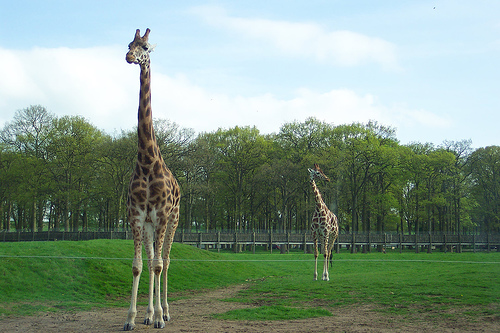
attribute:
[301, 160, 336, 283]
giraffe — very attractive , one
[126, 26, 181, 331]
giraffe — very attractive , one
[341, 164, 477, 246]
trees — green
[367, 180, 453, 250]
set — nice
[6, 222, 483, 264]
fence — wooden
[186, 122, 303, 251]
trees — tall, leafy, green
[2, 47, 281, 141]
clouds — white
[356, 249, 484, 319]
grass — well manicured, green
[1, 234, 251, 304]
hill — small, grassy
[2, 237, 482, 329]
enclosure — grassy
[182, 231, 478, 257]
platform — elevated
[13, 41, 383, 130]
clouds — white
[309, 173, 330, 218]
neck — long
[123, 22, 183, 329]
giraffe — large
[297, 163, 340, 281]
giraffe — large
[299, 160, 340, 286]
giraffe — tall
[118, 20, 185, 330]
giraffe — tall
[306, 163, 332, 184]
head — twisted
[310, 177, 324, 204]
neck — slanted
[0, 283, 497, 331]
patches — bare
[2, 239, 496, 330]
field — grassy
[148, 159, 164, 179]
spot — brown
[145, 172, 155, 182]
spot — brown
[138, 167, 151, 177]
spot — brown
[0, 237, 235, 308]
grass — bright green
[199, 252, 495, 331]
ground — flat